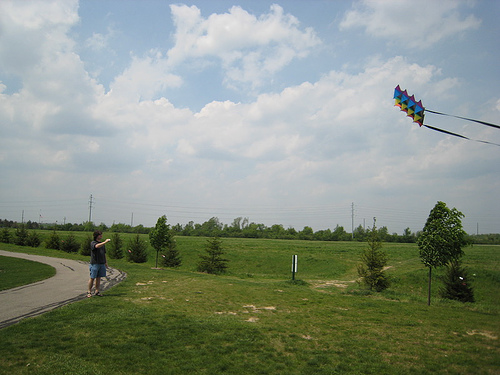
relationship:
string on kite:
[422, 109, 499, 146] [392, 83, 425, 123]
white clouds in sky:
[157, 97, 243, 136] [0, 0, 499, 234]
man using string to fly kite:
[86, 230, 111, 298] [349, 67, 443, 149]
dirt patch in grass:
[219, 293, 280, 325] [8, 220, 490, 372]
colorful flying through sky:
[408, 102, 421, 122] [288, 26, 356, 74]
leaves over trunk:
[431, 224, 453, 258] [422, 255, 438, 313]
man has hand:
[86, 230, 111, 298] [101, 236, 112, 244]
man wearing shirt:
[86, 230, 111, 298] [87, 239, 106, 274]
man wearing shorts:
[86, 230, 111, 298] [90, 262, 105, 277]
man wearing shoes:
[86, 230, 111, 298] [84, 289, 100, 299]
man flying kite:
[86, 230, 111, 298] [389, 80, 499, 155]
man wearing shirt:
[84, 224, 113, 303] [87, 240, 109, 267]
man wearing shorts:
[86, 230, 111, 298] [90, 263, 109, 278]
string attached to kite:
[427, 110, 479, 152] [392, 84, 499, 147]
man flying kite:
[86, 230, 111, 298] [392, 83, 425, 123]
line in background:
[5, 215, 497, 244] [6, 8, 499, 279]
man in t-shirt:
[86, 230, 111, 298] [92, 238, 108, 264]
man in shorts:
[86, 230, 111, 298] [90, 260, 107, 279]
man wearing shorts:
[86, 230, 111, 298] [85, 263, 107, 281]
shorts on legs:
[85, 263, 107, 281] [87, 261, 107, 294]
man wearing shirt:
[86, 230, 111, 298] [89, 240, 106, 264]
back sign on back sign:
[291, 254, 299, 280] [291, 254, 299, 280]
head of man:
[90, 227, 102, 240] [86, 230, 111, 298]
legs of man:
[89, 262, 103, 291] [84, 224, 113, 303]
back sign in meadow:
[278, 249, 305, 284] [203, 282, 430, 372]